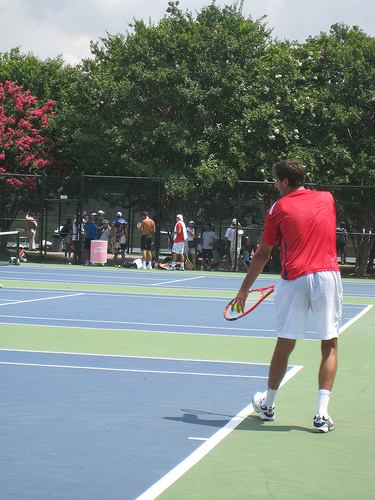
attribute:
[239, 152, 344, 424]
player — playing, preparing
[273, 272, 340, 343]
shorts — white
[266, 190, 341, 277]
shirt — red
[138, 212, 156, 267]
man — light skinned, shirtless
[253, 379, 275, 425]
foot — raised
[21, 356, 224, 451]
court — blue, green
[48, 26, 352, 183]
trees — leafy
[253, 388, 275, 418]
shoe — white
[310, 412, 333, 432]
shoe — white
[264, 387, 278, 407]
sock — white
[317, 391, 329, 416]
sock — white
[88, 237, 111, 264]
barrel — pink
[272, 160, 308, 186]
hair — brown